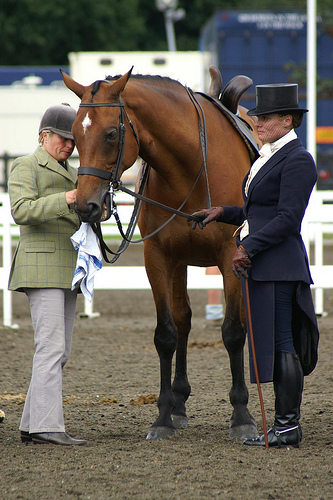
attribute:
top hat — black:
[246, 83, 309, 116]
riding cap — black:
[39, 102, 77, 143]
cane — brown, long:
[243, 266, 271, 446]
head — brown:
[56, 67, 140, 222]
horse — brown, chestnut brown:
[62, 71, 270, 449]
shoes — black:
[246, 347, 304, 446]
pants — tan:
[19, 287, 77, 436]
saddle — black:
[221, 70, 263, 148]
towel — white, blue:
[72, 219, 105, 319]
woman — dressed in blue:
[192, 82, 320, 444]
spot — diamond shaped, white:
[81, 112, 92, 135]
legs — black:
[144, 239, 257, 443]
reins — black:
[86, 88, 212, 263]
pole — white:
[305, 1, 317, 196]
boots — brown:
[19, 431, 86, 446]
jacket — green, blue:
[7, 145, 78, 291]